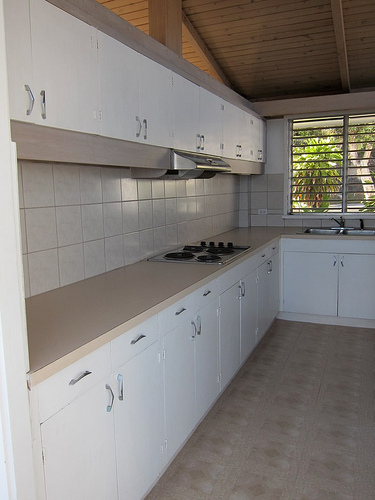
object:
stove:
[144, 241, 250, 265]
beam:
[146, 0, 184, 57]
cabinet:
[281, 243, 373, 327]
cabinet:
[31, 337, 159, 500]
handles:
[340, 256, 345, 267]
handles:
[116, 372, 126, 403]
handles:
[197, 315, 203, 337]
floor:
[250, 354, 346, 468]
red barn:
[100, 177, 122, 204]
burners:
[196, 253, 221, 262]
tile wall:
[157, 180, 190, 218]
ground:
[241, 52, 271, 91]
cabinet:
[9, 0, 92, 139]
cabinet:
[173, 54, 222, 155]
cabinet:
[222, 100, 248, 160]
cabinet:
[252, 113, 266, 162]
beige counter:
[27, 227, 281, 390]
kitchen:
[0, 0, 374, 500]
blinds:
[286, 113, 374, 217]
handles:
[190, 320, 196, 339]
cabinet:
[162, 304, 220, 469]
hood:
[131, 152, 231, 181]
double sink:
[304, 225, 375, 237]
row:
[10, 0, 268, 178]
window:
[289, 116, 375, 216]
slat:
[290, 162, 344, 170]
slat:
[293, 138, 346, 146]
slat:
[294, 129, 343, 140]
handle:
[24, 82, 34, 117]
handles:
[104, 382, 115, 412]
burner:
[161, 250, 196, 261]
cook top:
[143, 238, 254, 266]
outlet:
[257, 208, 267, 215]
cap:
[134, 115, 143, 139]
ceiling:
[229, 5, 336, 92]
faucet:
[329, 214, 346, 231]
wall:
[241, 118, 282, 233]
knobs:
[208, 241, 216, 248]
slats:
[291, 196, 341, 210]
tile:
[21, 163, 57, 210]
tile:
[54, 202, 84, 247]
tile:
[117, 199, 142, 236]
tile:
[176, 194, 188, 219]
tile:
[215, 191, 225, 215]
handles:
[142, 115, 148, 141]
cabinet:
[93, 25, 175, 150]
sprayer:
[358, 217, 364, 229]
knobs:
[226, 242, 234, 247]